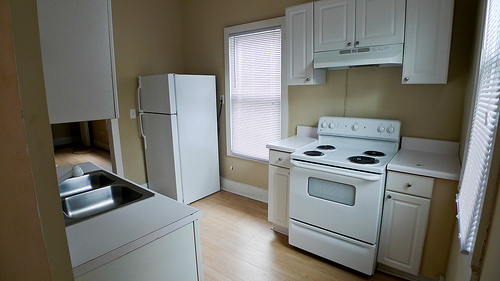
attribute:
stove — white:
[287, 114, 402, 276]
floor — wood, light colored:
[186, 189, 406, 280]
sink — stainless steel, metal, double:
[58, 168, 155, 227]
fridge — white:
[137, 73, 222, 205]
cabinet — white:
[283, 1, 328, 86]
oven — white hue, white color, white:
[288, 158, 386, 246]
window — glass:
[307, 175, 357, 207]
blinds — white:
[228, 25, 281, 164]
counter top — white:
[265, 124, 319, 154]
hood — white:
[312, 42, 403, 71]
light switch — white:
[129, 108, 136, 120]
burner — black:
[303, 149, 322, 157]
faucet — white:
[57, 164, 84, 185]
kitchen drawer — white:
[384, 170, 436, 201]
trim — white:
[220, 175, 269, 202]